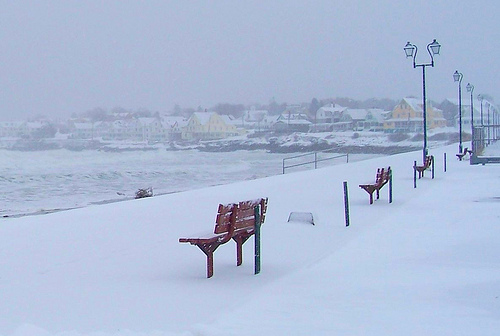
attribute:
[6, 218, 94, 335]
snow — white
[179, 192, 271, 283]
bench — red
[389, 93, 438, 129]
house — large, yellow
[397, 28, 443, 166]
lampost — tall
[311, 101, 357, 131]
building — back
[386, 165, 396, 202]
pole — gree, green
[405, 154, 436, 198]
poles — gree